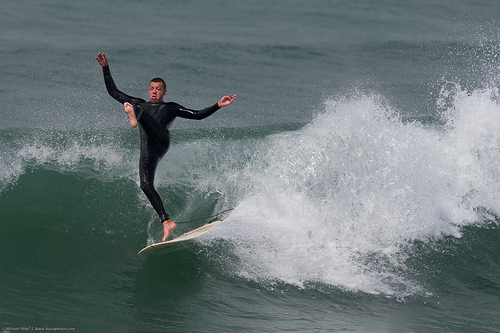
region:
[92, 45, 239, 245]
Man is wearing a wetsuit.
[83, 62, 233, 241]
Wetsuit is all one piece.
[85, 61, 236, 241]
The man's wetsuit is black.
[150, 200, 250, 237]
Man has legrope attached to his ankle.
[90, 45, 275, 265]
Man is standing on a surfboard.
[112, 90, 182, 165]
Man has one leg in the air.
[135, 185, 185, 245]
Man is on surfboard on tiptoe.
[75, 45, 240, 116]
Man's arms are outstretched.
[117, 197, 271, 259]
Surfboard is in the water.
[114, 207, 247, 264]
The surfboard is all white.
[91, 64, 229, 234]
this is a man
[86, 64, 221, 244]
the man is sea surfing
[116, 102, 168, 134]
the mans left leg is on air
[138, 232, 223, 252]
this is a surf board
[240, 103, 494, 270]
the waves are strong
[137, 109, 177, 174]
the man is wearing black costumes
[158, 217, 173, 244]
the mans left leg is on the surf board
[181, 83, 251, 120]
the mans hand is wide apart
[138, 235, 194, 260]
the surf board is white in color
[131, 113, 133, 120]
the man is light skinned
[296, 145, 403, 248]
part of a water splash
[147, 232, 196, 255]
part of a swimming board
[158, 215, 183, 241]
right foot of the man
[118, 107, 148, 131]
left foot of the man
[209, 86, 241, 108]
left hand of the man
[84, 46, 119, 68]
right hand of the man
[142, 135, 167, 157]
black costume of the man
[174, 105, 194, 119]
left bicep of the man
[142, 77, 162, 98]
face of the man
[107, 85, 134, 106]
bicep of the man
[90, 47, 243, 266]
A man riding a surf board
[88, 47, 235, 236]
A man wearing a black body suit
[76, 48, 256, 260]
A man losing his balance on a surf board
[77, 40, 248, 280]
A man falling off a surf board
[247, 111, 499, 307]
A breaking wave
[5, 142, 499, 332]
A surf boarder riding a small wave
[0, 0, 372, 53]
The calm ocean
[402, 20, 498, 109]
Spray from a breaking wave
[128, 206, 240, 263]
A foot tied to a surf board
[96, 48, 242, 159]
A man kicking the air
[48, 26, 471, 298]
This guy is surfing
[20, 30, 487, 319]
There is a wave in the photo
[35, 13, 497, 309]
This photo was taken on the ocean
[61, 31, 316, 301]
The guy has one leg up on the surfboard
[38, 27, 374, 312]
The guys is wearing a wetsuit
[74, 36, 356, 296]
The surfer is wearing a black wetsuit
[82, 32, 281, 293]
The guy is standing on a white surfboard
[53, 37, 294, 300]
The guy is wearing no shoes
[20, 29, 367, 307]
The surfer has his hands up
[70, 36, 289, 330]
The surfer only has one leg on the board